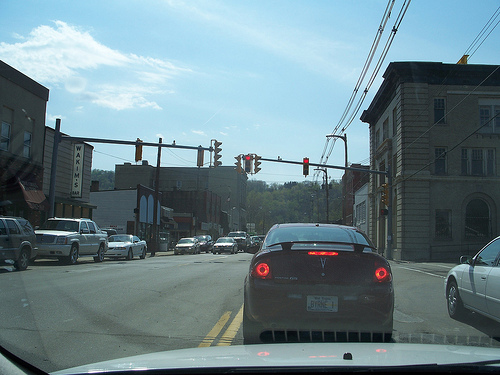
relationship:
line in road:
[194, 285, 261, 357] [51, 266, 190, 326]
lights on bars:
[64, 120, 371, 200] [152, 137, 173, 189]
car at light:
[246, 222, 395, 334] [303, 156, 311, 175]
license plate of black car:
[306, 287, 346, 322] [252, 205, 407, 335]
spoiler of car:
[259, 243, 384, 261] [246, 222, 395, 337]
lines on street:
[195, 328, 230, 347] [15, 213, 486, 361]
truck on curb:
[8, 225, 28, 254] [0, 245, 27, 280]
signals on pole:
[234, 147, 260, 177] [237, 157, 392, 177]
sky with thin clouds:
[2, 0, 499, 175] [0, 17, 197, 112]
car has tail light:
[246, 222, 395, 337] [255, 260, 270, 278]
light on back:
[247, 255, 277, 280] [245, 239, 393, 341]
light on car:
[247, 255, 277, 280] [246, 222, 395, 337]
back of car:
[245, 239, 393, 341] [246, 222, 395, 337]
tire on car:
[443, 274, 463, 321] [441, 231, 497, 332]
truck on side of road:
[39, 211, 111, 261] [0, 244, 490, 372]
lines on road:
[192, 299, 264, 347] [0, 244, 490, 372]